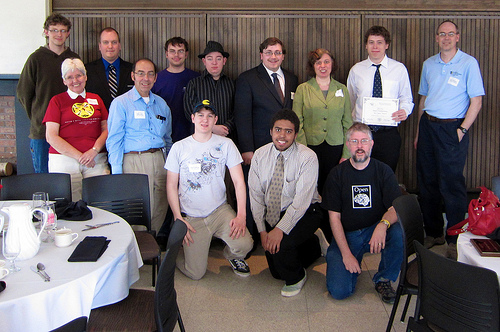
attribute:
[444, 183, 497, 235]
purse — red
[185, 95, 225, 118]
cap — baseball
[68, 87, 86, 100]
collar — white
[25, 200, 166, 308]
table — large, round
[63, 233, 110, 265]
napkin — black, cloth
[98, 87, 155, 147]
shirt — blue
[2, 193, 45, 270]
pitcher — tall, white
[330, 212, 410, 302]
jeans — blue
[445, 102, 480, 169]
watch — black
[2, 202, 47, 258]
container — white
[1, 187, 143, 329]
tablecloth — white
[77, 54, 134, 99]
jacket — black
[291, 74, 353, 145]
blazer — green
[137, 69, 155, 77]
eyeglasses — man's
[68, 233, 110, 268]
napkin — black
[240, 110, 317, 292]
man — young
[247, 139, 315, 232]
shirt — brown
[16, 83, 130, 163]
shirt — red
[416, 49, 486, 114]
shirt — blue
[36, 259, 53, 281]
spoon — silver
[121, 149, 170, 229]
pants — brown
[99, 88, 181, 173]
shirt — blue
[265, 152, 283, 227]
tie — brown, long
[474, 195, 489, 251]
purse — red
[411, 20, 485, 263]
people — posing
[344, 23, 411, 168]
people — posing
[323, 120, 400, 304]
people — posing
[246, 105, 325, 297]
people — posing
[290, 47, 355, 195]
people — posing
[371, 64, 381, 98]
neck tie — blue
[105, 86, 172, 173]
shirt — blue, button down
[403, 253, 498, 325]
chair — black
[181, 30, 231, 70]
hat — black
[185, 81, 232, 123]
cap — black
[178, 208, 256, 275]
pants — brown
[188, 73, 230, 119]
shirt — striped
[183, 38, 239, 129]
man — young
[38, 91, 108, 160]
shirt — red and yellow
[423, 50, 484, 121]
shirt — light blue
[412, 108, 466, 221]
pants — dark blue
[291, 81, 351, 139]
jacket — green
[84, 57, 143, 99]
suit jacket — black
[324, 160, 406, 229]
shirt — black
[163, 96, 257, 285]
man — young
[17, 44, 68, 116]
sweater — brown